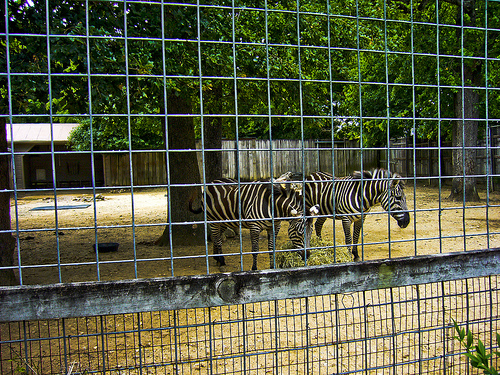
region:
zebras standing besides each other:
[175, 143, 420, 278]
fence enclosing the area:
[8, 14, 473, 354]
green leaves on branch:
[448, 308, 498, 365]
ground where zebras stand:
[16, 187, 482, 352]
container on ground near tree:
[81, 234, 128, 259]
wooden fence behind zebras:
[118, 131, 445, 190]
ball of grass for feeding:
[286, 233, 354, 272]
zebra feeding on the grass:
[193, 177, 339, 269]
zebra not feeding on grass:
[311, 158, 423, 252]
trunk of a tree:
[443, 98, 499, 204]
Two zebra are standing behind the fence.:
[188, 159, 413, 268]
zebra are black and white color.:
[200, 174, 410, 262]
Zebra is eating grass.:
[198, 183, 346, 268]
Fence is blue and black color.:
[28, 43, 440, 357]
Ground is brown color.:
[400, 183, 471, 305]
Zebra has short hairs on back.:
[348, 162, 393, 184]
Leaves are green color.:
[117, 25, 387, 111]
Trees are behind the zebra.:
[19, 11, 489, 206]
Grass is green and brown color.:
[274, 231, 349, 274]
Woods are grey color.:
[440, 93, 485, 212]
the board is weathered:
[318, 271, 357, 288]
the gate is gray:
[88, 142, 143, 202]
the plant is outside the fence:
[442, 314, 489, 366]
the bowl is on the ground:
[93, 238, 121, 254]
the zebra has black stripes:
[337, 186, 367, 210]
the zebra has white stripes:
[246, 192, 267, 216]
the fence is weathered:
[251, 145, 282, 172]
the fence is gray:
[173, 323, 235, 358]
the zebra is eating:
[295, 246, 319, 264]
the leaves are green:
[311, 34, 358, 80]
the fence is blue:
[70, 50, 279, 245]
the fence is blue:
[57, 54, 185, 201]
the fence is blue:
[34, 88, 249, 300]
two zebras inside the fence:
[162, 123, 439, 294]